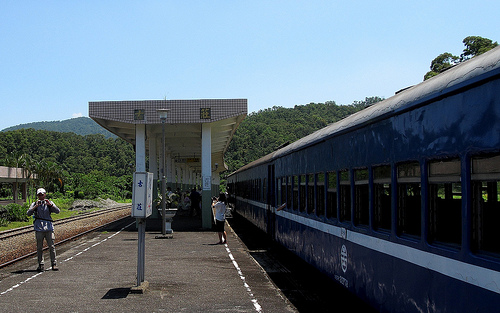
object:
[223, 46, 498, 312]
train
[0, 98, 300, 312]
station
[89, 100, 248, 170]
covering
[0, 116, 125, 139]
mountain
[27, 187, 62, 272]
man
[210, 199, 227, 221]
shirt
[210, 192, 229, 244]
woman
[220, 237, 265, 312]
line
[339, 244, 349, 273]
insignia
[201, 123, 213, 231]
support post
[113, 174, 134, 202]
trees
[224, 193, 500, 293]
stripe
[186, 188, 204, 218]
person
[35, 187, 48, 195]
cap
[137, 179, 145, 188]
letters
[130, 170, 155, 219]
box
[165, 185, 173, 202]
people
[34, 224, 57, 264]
pants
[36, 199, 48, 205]
camera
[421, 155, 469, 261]
windows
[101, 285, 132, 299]
shadow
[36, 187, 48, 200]
head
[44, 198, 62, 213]
arm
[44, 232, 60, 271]
leg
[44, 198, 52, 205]
hand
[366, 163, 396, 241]
window